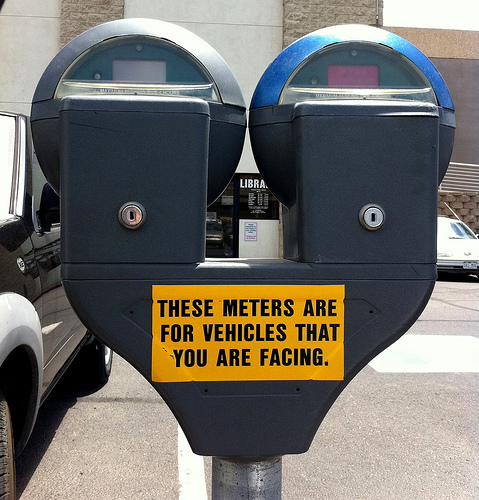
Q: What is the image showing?
A: It is showing a parking lot.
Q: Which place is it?
A: It is a parking lot.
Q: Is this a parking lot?
A: Yes, it is a parking lot.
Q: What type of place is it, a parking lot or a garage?
A: It is a parking lot.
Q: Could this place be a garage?
A: No, it is a parking lot.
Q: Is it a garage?
A: No, it is a parking lot.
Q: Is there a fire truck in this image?
A: No, there are no fire trucks.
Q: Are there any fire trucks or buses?
A: No, there are no fire trucks or buses.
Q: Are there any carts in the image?
A: No, there are no carts.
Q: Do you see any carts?
A: No, there are no carts.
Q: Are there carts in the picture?
A: No, there are no carts.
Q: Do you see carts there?
A: No, there are no carts.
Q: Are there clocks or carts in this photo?
A: No, there are no carts or clocks.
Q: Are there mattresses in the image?
A: No, there are no mattresses.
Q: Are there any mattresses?
A: No, there are no mattresses.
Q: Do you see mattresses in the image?
A: No, there are no mattresses.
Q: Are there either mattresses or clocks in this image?
A: No, there are no mattresses or clocks.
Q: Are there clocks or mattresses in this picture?
A: No, there are no mattresses or clocks.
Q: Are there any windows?
A: Yes, there is a window.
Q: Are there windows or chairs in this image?
A: Yes, there is a window.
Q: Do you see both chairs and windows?
A: No, there is a window but no chairs.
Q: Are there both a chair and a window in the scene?
A: No, there is a window but no chairs.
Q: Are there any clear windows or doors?
A: Yes, there is a clear window.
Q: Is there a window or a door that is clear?
A: Yes, the window is clear.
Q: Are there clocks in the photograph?
A: No, there are no clocks.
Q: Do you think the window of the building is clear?
A: Yes, the window is clear.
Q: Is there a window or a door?
A: Yes, there is a window.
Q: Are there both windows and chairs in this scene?
A: No, there is a window but no chairs.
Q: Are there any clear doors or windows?
A: Yes, there is a clear window.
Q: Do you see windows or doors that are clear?
A: Yes, the window is clear.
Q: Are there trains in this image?
A: No, there are no trains.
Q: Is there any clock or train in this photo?
A: No, there are no trains or clocks.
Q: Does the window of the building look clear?
A: Yes, the window is clear.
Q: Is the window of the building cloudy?
A: No, the window is clear.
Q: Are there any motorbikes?
A: No, there are no motorbikes.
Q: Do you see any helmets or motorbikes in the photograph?
A: No, there are no motorbikes or helmets.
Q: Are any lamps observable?
A: No, there are no lamps.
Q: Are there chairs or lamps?
A: No, there are no lamps or chairs.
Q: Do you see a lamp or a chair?
A: No, there are no lamps or chairs.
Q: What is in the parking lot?
A: The car is in the parking lot.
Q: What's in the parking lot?
A: The car is in the parking lot.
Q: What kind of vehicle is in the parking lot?
A: The vehicle is a car.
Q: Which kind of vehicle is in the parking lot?
A: The vehicle is a car.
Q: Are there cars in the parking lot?
A: Yes, there is a car in the parking lot.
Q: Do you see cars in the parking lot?
A: Yes, there is a car in the parking lot.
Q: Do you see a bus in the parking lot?
A: No, there is a car in the parking lot.